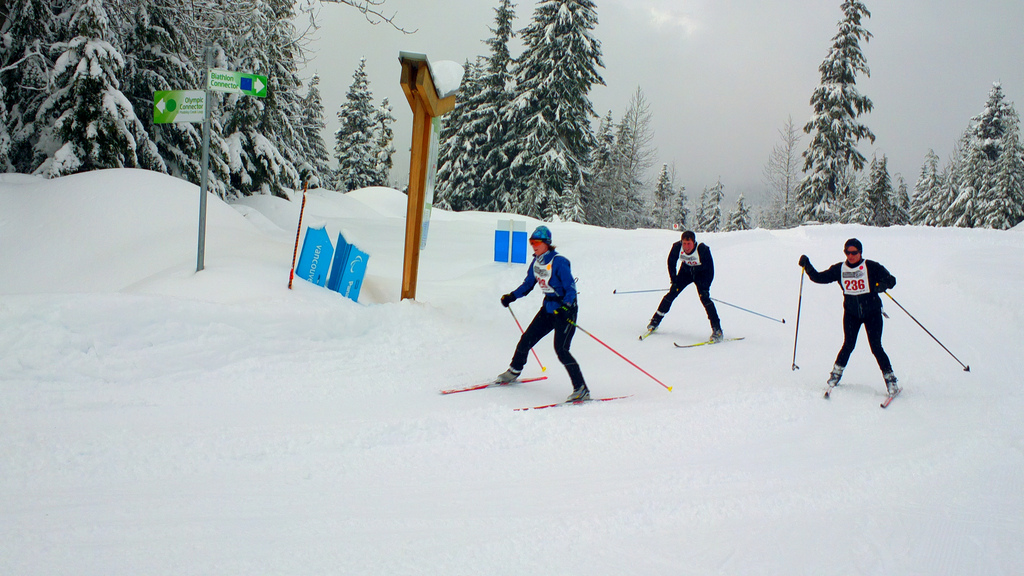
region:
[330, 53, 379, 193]
Tall tree covered in snow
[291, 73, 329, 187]
Tall tree covered in snow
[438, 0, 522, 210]
Tall tree covered in snow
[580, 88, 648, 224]
Tall tree covered in snow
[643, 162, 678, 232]
Tall tree covered in snow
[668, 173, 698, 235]
Tall tree covered in snow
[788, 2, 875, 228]
Tall tree covered in snow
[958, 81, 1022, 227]
Tall tree covered in snow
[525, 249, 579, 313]
man wearing a blue jacket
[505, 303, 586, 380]
Man wearing black pants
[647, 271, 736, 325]
Man wearing black pants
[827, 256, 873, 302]
sign with number on the shirt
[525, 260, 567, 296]
sign with number on the shirt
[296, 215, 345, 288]
blue bin in the snow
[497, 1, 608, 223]
tree is covered in snow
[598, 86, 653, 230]
tree is covered in snow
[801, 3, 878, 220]
tree is covered in snow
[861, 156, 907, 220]
tree is covered in snow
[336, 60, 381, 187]
tree is covered in snow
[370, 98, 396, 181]
tree is covered in snow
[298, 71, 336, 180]
tree is covered in snow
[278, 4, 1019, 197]
The cloudy sky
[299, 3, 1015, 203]
A cloudy sky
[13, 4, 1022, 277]
A forest of trees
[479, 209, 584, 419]
man skiing during race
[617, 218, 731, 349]
man skiing during race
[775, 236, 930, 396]
man skiing during race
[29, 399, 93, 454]
white snow on hill side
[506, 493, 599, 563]
white snow on hill side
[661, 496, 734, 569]
white snow on hill side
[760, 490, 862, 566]
white snow on hill side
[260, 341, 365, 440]
white snow on hill side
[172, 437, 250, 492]
white snow on hill side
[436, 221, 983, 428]
three people skiing in winter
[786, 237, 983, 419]
a woman wearing skis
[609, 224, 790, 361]
a person holding two ski poles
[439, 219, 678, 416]
a person in a blue hat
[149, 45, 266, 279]
a pole with two green signs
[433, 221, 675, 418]
person holding two orange ski poles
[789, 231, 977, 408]
person wearing a competition number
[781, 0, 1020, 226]
snow covered pine trees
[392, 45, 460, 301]
brown wooden sign post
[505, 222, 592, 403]
person in a blue coat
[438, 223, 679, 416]
a woman that is skiing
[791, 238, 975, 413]
a person that is skiing